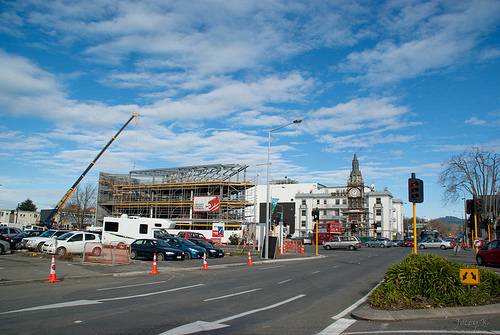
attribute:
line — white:
[205, 287, 262, 303]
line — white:
[270, 277, 293, 285]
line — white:
[307, 270, 320, 277]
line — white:
[347, 260, 356, 266]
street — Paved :
[206, 234, 403, 331]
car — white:
[40, 231, 102, 254]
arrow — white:
[163, 293, 304, 333]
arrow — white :
[139, 293, 316, 333]